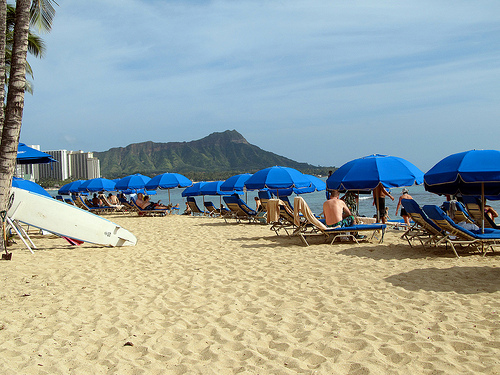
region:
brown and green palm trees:
[0, 0, 58, 233]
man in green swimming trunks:
[324, 189, 359, 225]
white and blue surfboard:
[6, 188, 136, 245]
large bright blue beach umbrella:
[145, 171, 190, 211]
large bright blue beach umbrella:
[182, 180, 207, 214]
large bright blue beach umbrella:
[222, 171, 252, 206]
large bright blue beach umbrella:
[245, 165, 307, 198]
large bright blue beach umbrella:
[328, 153, 421, 220]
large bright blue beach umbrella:
[424, 149, 499, 253]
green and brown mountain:
[89, 129, 341, 177]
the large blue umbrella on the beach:
[59, 178, 79, 195]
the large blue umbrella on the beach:
[82, 176, 113, 191]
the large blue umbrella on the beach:
[117, 171, 147, 190]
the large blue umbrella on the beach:
[143, 171, 189, 189]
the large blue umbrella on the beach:
[182, 181, 205, 194]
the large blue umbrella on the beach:
[197, 181, 235, 197]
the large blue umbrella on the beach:
[225, 174, 252, 192]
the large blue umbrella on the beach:
[247, 168, 304, 190]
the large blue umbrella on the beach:
[266, 172, 321, 198]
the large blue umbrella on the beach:
[325, 154, 423, 191]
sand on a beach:
[104, 256, 308, 364]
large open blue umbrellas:
[272, 140, 497, 296]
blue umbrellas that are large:
[212, 139, 458, 269]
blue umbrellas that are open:
[162, 110, 497, 293]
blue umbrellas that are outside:
[222, 124, 469, 284]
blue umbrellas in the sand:
[204, 99, 486, 286]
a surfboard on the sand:
[37, 145, 197, 353]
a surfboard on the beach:
[29, 161, 158, 296]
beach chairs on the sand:
[183, 118, 448, 345]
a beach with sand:
[129, 249, 197, 318]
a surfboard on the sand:
[7, 139, 121, 259]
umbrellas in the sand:
[174, 154, 476, 346]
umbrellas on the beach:
[189, 146, 491, 295]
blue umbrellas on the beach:
[207, 111, 496, 270]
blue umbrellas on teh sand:
[154, 131, 496, 280]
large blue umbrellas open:
[189, 147, 496, 302]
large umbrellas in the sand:
[234, 111, 499, 306]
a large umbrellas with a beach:
[214, 122, 496, 298]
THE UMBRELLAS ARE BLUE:
[50, 146, 497, 209]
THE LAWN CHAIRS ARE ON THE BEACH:
[52, 188, 494, 260]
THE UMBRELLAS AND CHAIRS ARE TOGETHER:
[55, 141, 497, 251]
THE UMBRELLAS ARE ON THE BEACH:
[48, 150, 495, 205]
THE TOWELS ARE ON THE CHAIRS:
[261, 191, 331, 236]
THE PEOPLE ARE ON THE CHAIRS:
[27, 150, 493, 257]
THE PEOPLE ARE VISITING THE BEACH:
[55, 168, 495, 284]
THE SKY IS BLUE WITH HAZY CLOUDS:
[3, 0, 497, 195]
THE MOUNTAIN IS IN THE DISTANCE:
[37, 120, 337, 192]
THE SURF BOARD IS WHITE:
[0, 190, 141, 247]